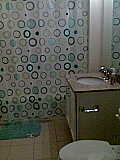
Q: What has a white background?
A: The shower curtain.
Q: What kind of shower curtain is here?
A: Plastic with many small circles.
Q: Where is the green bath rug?
A: Next to the tub.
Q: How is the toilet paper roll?
A: Devoid of toilet paper.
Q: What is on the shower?
A: Shower curtain.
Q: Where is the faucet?
A: Above the sink.